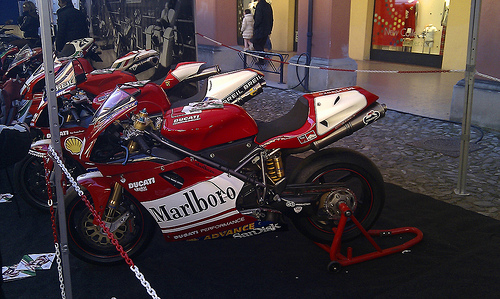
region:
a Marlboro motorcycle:
[67, 97, 387, 251]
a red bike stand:
[323, 191, 441, 273]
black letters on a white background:
[157, 201, 194, 222]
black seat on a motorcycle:
[234, 85, 307, 142]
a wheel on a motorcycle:
[302, 154, 402, 225]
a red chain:
[81, 199, 135, 267]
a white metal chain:
[60, 160, 82, 198]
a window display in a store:
[379, 8, 444, 54]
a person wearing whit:
[234, 11, 261, 56]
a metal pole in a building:
[42, 27, 76, 297]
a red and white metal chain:
[45, 146, 180, 296]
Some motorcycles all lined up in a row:
[7, 28, 389, 265]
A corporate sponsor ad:
[142, 175, 244, 230]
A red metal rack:
[323, 200, 427, 262]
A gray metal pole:
[35, 1, 86, 297]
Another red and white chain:
[195, 29, 468, 82]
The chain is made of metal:
[195, 27, 463, 82]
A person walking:
[237, 6, 254, 54]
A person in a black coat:
[253, 0, 275, 68]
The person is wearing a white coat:
[237, 7, 252, 59]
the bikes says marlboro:
[153, 182, 234, 230]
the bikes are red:
[0, 37, 417, 254]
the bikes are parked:
[0, 31, 412, 258]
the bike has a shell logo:
[66, 139, 86, 159]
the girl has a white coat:
[240, 10, 255, 42]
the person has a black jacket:
[55, 6, 92, 41]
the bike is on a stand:
[320, 205, 423, 257]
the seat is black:
[253, 100, 309, 132]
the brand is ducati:
[128, 177, 165, 190]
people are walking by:
[20, 2, 270, 62]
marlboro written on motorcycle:
[128, 170, 261, 241]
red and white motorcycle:
[64, 102, 412, 256]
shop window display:
[366, 5, 478, 85]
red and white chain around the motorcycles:
[44, 136, 168, 296]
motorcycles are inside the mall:
[2, 3, 474, 295]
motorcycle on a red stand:
[309, 186, 451, 278]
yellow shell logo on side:
[54, 130, 94, 165]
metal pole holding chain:
[30, 8, 87, 294]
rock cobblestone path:
[360, 91, 498, 213]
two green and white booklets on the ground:
[4, 251, 70, 293]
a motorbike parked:
[54, 81, 388, 273]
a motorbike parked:
[14, 53, 270, 213]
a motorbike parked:
[15, 60, 220, 128]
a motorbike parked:
[15, 39, 95, 104]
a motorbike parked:
[0, 32, 30, 72]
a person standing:
[53, 0, 85, 49]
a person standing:
[15, 0, 37, 36]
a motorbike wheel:
[283, 142, 390, 239]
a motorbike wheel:
[50, 188, 155, 265]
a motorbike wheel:
[13, 149, 83, 216]